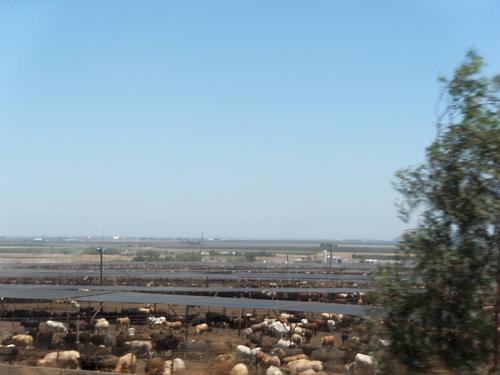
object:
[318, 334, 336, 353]
cows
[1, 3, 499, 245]
sky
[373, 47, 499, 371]
tree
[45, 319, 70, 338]
cow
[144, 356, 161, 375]
cow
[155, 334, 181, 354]
cow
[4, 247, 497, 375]
pasture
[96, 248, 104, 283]
pole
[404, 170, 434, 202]
branch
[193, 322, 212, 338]
cows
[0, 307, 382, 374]
fence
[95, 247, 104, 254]
light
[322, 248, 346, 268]
building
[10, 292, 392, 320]
water